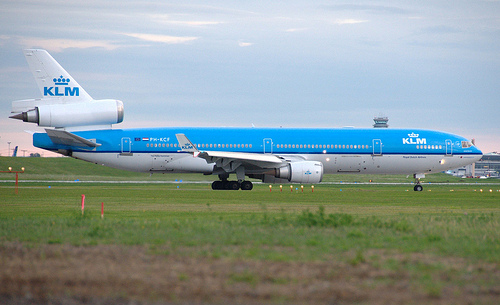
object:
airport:
[473, 152, 500, 178]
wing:
[178, 148, 289, 172]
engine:
[266, 160, 324, 184]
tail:
[7, 49, 124, 130]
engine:
[9, 99, 125, 126]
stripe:
[42, 151, 485, 158]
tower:
[372, 117, 391, 128]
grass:
[1, 203, 498, 245]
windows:
[201, 143, 253, 149]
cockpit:
[461, 141, 473, 148]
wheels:
[239, 181, 254, 191]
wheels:
[413, 184, 424, 192]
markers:
[78, 191, 86, 217]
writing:
[43, 86, 79, 96]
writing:
[402, 137, 427, 144]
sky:
[0, 0, 500, 158]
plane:
[9, 47, 486, 191]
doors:
[119, 136, 133, 155]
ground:
[1, 157, 498, 302]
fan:
[277, 164, 293, 180]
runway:
[1, 177, 210, 191]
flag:
[141, 136, 149, 141]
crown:
[52, 74, 72, 86]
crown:
[407, 131, 422, 138]